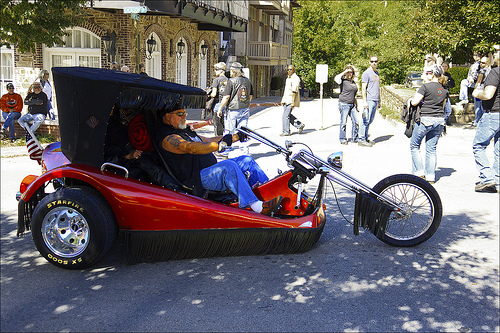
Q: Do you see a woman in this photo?
A: Yes, there is a woman.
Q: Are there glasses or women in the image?
A: Yes, there is a woman.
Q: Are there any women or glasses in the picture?
A: Yes, there is a woman.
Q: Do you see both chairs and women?
A: No, there is a woman but no chairs.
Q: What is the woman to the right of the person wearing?
A: The woman is wearing jeans.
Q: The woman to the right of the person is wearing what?
A: The woman is wearing jeans.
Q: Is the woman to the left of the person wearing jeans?
A: Yes, the woman is wearing jeans.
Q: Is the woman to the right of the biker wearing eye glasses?
A: No, the woman is wearing jeans.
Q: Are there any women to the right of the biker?
A: Yes, there is a woman to the right of the biker.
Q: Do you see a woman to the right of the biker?
A: Yes, there is a woman to the right of the biker.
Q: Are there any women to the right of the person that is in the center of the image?
A: Yes, there is a woman to the right of the biker.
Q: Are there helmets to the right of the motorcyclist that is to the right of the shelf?
A: No, there is a woman to the right of the biker.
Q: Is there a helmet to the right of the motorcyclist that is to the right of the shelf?
A: No, there is a woman to the right of the biker.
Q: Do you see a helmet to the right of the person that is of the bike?
A: No, there is a woman to the right of the biker.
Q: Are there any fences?
A: No, there are no fences.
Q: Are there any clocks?
A: No, there are no clocks.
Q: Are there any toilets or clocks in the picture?
A: No, there are no clocks or toilets.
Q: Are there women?
A: Yes, there is a woman.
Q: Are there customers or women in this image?
A: Yes, there is a woman.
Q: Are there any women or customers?
A: Yes, there is a woman.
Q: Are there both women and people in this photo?
A: Yes, there are both a woman and a person.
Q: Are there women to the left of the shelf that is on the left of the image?
A: Yes, there is a woman to the left of the shelf.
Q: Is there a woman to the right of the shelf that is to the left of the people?
A: No, the woman is to the left of the shelf.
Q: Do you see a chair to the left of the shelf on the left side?
A: No, there is a woman to the left of the shelf.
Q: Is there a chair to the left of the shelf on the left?
A: No, there is a woman to the left of the shelf.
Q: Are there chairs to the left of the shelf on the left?
A: No, there is a woman to the left of the shelf.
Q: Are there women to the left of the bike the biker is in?
A: Yes, there is a woman to the left of the bike.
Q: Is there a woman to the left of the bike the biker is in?
A: Yes, there is a woman to the left of the bike.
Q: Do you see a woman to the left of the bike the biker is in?
A: Yes, there is a woman to the left of the bike.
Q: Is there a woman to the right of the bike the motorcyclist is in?
A: No, the woman is to the left of the bike.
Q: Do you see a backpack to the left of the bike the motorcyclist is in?
A: No, there is a woman to the left of the bike.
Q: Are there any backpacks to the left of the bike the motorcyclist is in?
A: No, there is a woman to the left of the bike.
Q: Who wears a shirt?
A: The woman wears a shirt.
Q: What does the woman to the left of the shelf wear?
A: The woman wears a shirt.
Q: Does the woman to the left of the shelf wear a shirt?
A: Yes, the woman wears a shirt.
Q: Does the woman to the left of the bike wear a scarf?
A: No, the woman wears a shirt.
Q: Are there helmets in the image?
A: No, there are no helmets.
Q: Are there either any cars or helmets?
A: No, there are no helmets or cars.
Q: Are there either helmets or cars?
A: No, there are no helmets or cars.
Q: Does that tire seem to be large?
A: Yes, the tire is large.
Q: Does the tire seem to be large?
A: Yes, the tire is large.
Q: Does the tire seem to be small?
A: No, the tire is large.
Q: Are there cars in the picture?
A: No, there are no cars.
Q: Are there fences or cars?
A: No, there are no cars or fences.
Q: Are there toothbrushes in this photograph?
A: No, there are no toothbrushes.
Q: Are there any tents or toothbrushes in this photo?
A: No, there are no toothbrushes or tents.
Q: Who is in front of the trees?
A: The crowd is in front of the trees.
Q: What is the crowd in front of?
A: The crowd is in front of the trees.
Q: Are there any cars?
A: No, there are no cars.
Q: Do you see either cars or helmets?
A: No, there are no cars or helmets.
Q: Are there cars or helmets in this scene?
A: No, there are no cars or helmets.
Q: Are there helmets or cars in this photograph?
A: No, there are no cars or helmets.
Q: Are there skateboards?
A: No, there are no skateboards.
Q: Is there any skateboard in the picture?
A: No, there are no skateboards.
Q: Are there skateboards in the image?
A: No, there are no skateboards.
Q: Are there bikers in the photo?
A: Yes, there is a biker.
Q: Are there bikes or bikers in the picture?
A: Yes, there is a biker.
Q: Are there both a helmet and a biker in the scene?
A: No, there is a biker but no helmets.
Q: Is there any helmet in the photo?
A: No, there are no helmets.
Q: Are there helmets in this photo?
A: No, there are no helmets.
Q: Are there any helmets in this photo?
A: No, there are no helmets.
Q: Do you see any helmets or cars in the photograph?
A: No, there are no helmets or cars.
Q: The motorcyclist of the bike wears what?
A: The biker wears jeans.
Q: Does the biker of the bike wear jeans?
A: Yes, the motorcyclist wears jeans.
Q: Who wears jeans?
A: The biker wears jeans.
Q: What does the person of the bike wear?
A: The biker wears jeans.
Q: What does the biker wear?
A: The biker wears jeans.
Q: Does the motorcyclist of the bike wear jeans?
A: Yes, the motorcyclist wears jeans.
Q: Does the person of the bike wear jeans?
A: Yes, the motorcyclist wears jeans.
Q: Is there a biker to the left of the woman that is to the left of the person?
A: Yes, there is a biker to the left of the woman.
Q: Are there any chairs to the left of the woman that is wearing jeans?
A: No, there is a biker to the left of the woman.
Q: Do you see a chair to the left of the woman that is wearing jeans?
A: No, there is a biker to the left of the woman.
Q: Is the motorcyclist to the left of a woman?
A: Yes, the motorcyclist is to the left of a woman.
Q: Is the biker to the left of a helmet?
A: No, the biker is to the left of a woman.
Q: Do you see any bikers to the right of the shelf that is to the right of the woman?
A: Yes, there is a biker to the right of the shelf.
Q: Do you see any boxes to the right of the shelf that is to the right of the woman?
A: No, there is a biker to the right of the shelf.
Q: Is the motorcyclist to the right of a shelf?
A: Yes, the motorcyclist is to the right of a shelf.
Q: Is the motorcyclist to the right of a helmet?
A: No, the motorcyclist is to the right of a shelf.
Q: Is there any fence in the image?
A: No, there are no fences.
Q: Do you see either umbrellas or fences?
A: No, there are no fences or umbrellas.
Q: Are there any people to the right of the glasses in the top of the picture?
A: Yes, there are people to the right of the glasses.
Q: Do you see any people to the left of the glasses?
A: No, the people are to the right of the glasses.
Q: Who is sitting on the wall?
A: The people are sitting on the wall.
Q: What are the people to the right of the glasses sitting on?
A: The people are sitting on the wall.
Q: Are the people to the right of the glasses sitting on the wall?
A: Yes, the people are sitting on the wall.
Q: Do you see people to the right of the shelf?
A: Yes, there are people to the right of the shelf.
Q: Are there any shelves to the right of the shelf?
A: No, there are people to the right of the shelf.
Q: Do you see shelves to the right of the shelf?
A: No, there are people to the right of the shelf.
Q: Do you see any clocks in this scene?
A: No, there are no clocks.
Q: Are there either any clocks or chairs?
A: No, there are no clocks or chairs.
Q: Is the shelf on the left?
A: Yes, the shelf is on the left of the image.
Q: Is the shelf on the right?
A: No, the shelf is on the left of the image.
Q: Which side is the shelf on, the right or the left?
A: The shelf is on the left of the image.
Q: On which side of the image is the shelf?
A: The shelf is on the left of the image.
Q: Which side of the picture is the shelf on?
A: The shelf is on the left of the image.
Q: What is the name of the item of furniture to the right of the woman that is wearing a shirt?
A: The piece of furniture is a shelf.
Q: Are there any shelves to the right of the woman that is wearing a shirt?
A: Yes, there is a shelf to the right of the woman.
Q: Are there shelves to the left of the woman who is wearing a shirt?
A: No, the shelf is to the right of the woman.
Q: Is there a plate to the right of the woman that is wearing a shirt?
A: No, there is a shelf to the right of the woman.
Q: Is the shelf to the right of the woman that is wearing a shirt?
A: Yes, the shelf is to the right of the woman.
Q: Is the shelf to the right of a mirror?
A: No, the shelf is to the right of the woman.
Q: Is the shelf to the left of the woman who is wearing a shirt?
A: No, the shelf is to the right of the woman.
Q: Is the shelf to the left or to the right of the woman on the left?
A: The shelf is to the right of the woman.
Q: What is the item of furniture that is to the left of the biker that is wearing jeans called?
A: The piece of furniture is a shelf.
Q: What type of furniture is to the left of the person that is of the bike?
A: The piece of furniture is a shelf.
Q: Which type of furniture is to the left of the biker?
A: The piece of furniture is a shelf.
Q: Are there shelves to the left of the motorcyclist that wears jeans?
A: Yes, there is a shelf to the left of the biker.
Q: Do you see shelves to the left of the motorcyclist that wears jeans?
A: Yes, there is a shelf to the left of the biker.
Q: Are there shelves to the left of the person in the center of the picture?
A: Yes, there is a shelf to the left of the biker.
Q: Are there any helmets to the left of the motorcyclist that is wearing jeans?
A: No, there is a shelf to the left of the biker.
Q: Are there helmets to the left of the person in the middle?
A: No, there is a shelf to the left of the biker.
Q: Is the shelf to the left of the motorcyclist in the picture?
A: Yes, the shelf is to the left of the motorcyclist.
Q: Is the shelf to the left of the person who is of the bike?
A: Yes, the shelf is to the left of the motorcyclist.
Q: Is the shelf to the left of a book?
A: No, the shelf is to the left of the motorcyclist.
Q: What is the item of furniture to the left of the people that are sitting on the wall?
A: The piece of furniture is a shelf.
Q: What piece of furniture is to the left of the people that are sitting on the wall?
A: The piece of furniture is a shelf.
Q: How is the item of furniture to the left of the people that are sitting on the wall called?
A: The piece of furniture is a shelf.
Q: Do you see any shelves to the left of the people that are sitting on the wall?
A: Yes, there is a shelf to the left of the people.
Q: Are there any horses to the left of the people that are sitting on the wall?
A: No, there is a shelf to the left of the people.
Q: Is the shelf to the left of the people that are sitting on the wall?
A: Yes, the shelf is to the left of the people.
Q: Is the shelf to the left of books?
A: No, the shelf is to the left of the people.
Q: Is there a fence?
A: No, there are no fences.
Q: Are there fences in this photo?
A: No, there are no fences.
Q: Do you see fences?
A: No, there are no fences.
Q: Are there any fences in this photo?
A: No, there are no fences.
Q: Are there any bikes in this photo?
A: Yes, there is a bike.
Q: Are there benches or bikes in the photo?
A: Yes, there is a bike.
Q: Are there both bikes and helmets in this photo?
A: No, there is a bike but no helmets.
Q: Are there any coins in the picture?
A: No, there are no coins.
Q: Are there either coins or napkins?
A: No, there are no coins or napkins.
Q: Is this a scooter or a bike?
A: This is a bike.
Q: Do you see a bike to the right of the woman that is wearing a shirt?
A: Yes, there is a bike to the right of the woman.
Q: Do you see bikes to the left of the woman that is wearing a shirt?
A: No, the bike is to the right of the woman.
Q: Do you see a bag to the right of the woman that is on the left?
A: No, there is a bike to the right of the woman.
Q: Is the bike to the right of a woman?
A: Yes, the bike is to the right of a woman.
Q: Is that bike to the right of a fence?
A: No, the bike is to the right of a woman.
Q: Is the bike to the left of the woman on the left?
A: No, the bike is to the right of the woman.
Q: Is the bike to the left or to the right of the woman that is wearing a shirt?
A: The bike is to the right of the woman.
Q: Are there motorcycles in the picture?
A: Yes, there is a motorcycle.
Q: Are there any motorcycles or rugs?
A: Yes, there is a motorcycle.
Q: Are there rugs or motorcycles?
A: Yes, there is a motorcycle.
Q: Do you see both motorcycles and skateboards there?
A: No, there is a motorcycle but no skateboards.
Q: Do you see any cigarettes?
A: No, there are no cigarettes.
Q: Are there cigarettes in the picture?
A: No, there are no cigarettes.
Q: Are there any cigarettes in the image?
A: No, there are no cigarettes.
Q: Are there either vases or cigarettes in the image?
A: No, there are no cigarettes or vases.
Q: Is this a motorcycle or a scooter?
A: This is a motorcycle.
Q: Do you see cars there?
A: No, there are no cars.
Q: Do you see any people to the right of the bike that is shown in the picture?
A: Yes, there is a person to the right of the bike.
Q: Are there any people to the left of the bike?
A: No, the person is to the right of the bike.